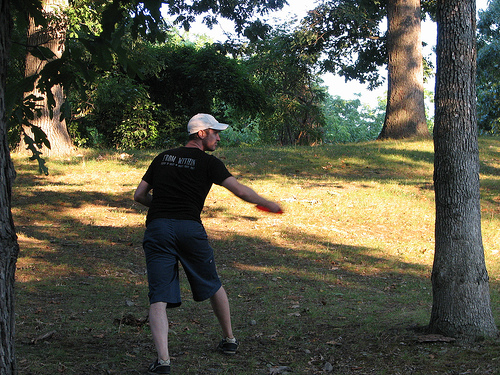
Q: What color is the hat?
A: White.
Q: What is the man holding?
A: Frisbee.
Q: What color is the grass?
A: Green.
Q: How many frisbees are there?
A: One.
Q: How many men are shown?
A: One.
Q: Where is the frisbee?
A: Man's hand.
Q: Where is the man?
A: In the grass.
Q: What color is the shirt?
A: Black.